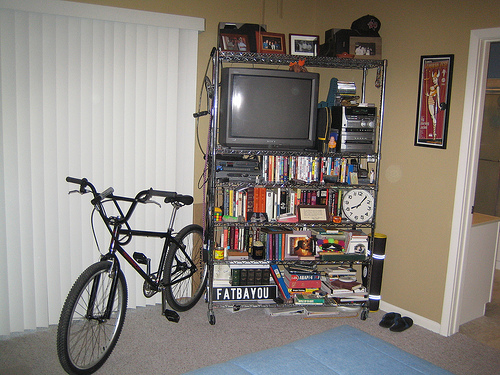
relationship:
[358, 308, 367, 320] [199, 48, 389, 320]
wheel on stand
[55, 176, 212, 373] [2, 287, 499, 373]
bicycle on carpet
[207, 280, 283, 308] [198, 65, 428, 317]
sign on shelf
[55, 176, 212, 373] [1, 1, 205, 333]
bicycle by blinds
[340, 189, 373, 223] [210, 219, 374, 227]
clock on shelf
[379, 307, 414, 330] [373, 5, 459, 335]
shoes next to wall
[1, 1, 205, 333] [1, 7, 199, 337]
blinds covering window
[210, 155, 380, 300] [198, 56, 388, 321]
books on shelf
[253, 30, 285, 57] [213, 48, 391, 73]
picture on shelf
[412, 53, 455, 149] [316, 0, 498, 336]
painting on wall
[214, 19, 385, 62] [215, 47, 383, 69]
frames on shelf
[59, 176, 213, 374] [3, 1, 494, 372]
bicycle in room